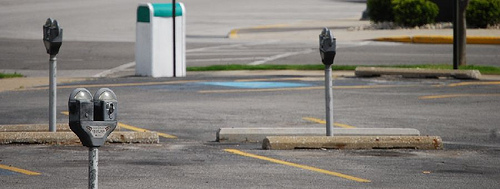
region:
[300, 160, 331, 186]
Yellow line on payment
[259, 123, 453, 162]
Concrete barrier in parking lot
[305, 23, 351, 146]
parking meter in parking lot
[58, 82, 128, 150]
parking meters on a pole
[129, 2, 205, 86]
Green and white trash can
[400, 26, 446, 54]
yellow safety paint on a curb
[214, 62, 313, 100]
a water puddle in parking lot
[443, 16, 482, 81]
a barren tree near parking lot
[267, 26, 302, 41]
A concrete side walk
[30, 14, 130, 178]
Four parking meters in parking lot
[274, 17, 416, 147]
parking meter by a parking spot.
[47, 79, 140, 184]
Silver parking meter.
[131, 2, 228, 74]
white and green trash can on the ground.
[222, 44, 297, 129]
Blue spot on the ground.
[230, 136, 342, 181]
Yellow stripe on the road.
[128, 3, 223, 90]
Trash can.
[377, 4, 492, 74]
Trees in the background.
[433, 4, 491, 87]
Trunk of the tree.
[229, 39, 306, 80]
Green grass on the median.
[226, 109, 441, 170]
Parking spot markers on the ground.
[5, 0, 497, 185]
Exterior shot, daytime, season, probably after early spring, before late fall.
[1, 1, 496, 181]
Man-made landscape, with some manipulated, natural elements.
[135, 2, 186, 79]
Post, in front of white and blue mailbox.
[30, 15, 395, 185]
Grey, parking meters.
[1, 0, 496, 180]
Street, centered between two parking areas.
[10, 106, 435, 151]
Cement, parking spot demarcations.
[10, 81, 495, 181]
Parking lot asphalt with yellow lines.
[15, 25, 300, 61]
Patched area on center road, with white lines.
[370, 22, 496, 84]
Curbs on either side of center road.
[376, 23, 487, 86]
Yellow paint, hedges, on one curb, grass, sidewalk, pole and tree.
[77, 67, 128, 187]
a double parking meter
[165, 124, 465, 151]
two concrete curbs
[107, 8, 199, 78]
a green and white garbage can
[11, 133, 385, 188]
yellow lines painted on the pavement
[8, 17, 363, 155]
three parking meters in a lot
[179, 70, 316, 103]
a painted blue square on the pavement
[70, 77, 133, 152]
a grey parking meter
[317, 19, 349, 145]
a parking meter on a post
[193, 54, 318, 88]
a patch of green grass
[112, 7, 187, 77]
a metal garbage can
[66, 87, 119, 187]
two meters on the road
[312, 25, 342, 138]
one meter on the road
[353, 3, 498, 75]
green tree with a trunk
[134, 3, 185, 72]
green and white garbage can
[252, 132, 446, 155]
cement slab on the road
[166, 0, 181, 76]
black pole in front of the garbage can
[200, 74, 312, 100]
blue on the road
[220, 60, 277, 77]
grass by the sidewalk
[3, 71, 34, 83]
patch of grass on the road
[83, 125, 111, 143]
sign on the meter